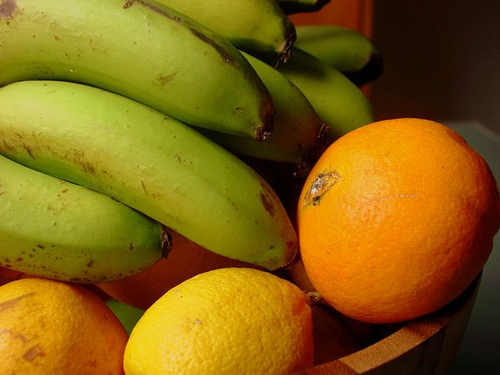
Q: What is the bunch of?
A: Bananas.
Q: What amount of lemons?
A: One.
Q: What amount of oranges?
A: One.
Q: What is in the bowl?
A: Fruit.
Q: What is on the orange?
A: Marks.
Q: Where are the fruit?
A: Bowl.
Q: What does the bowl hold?
A: Fruit.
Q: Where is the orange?
A: Bowl.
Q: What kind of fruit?
A: Lemon.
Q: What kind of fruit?
A: Banana.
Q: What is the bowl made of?
A: Wood.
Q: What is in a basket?
A: A orange.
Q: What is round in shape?
A: A lemon.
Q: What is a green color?
A: A banana.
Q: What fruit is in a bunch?
A: Bananas.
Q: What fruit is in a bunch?
A: Bananas.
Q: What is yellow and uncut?
A: The lemon.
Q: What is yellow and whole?
A: A lemon.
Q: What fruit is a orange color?
A: A orange.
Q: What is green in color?
A: Bananas.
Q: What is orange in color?
A: Oranges.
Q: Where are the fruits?
A: In a basket.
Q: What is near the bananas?
A: Oranges.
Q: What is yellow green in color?
A: Bananas.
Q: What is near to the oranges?
A: Bananas.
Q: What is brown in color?
A: A basket.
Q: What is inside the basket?
A: Fruits.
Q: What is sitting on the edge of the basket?
A: Orange.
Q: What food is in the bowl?
A: Fruits.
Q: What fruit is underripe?
A: Bananas.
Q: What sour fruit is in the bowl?
A: Lemon.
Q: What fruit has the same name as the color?
A: Orange.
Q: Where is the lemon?
A: Near the orange.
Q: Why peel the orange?
A: For sections.